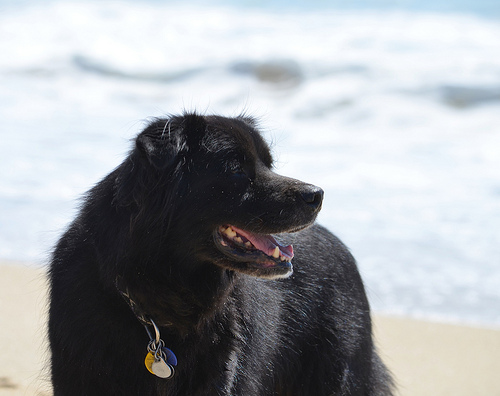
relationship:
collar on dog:
[112, 272, 182, 379] [39, 97, 399, 394]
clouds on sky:
[289, 12, 486, 92] [2, 2, 497, 121]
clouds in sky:
[287, 21, 462, 72] [68, 9, 392, 85]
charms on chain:
[141, 347, 182, 377] [95, 259, 139, 329]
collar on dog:
[112, 277, 192, 338] [39, 97, 399, 394]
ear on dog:
[135, 112, 193, 169] [39, 97, 399, 394]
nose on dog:
[295, 184, 322, 209] [39, 97, 399, 394]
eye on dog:
[220, 157, 247, 178] [32, 68, 412, 393]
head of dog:
[128, 106, 323, 280] [39, 97, 399, 394]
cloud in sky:
[280, 17, 490, 71] [209, 2, 489, 17]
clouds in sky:
[0, 4, 472, 54] [211, 0, 401, 7]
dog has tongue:
[39, 97, 399, 394] [227, 225, 292, 259]